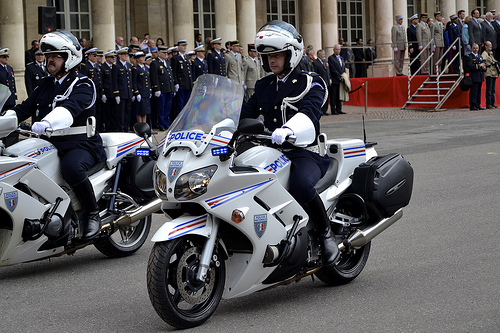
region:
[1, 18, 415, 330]
Pair of policemen on motorcycles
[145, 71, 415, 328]
Red, white, and blue police motorcycle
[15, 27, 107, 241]
Uniformed policeman with moustache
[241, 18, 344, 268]
Motorcycle police officer in formal uniform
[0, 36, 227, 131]
Line of people in blue uniforms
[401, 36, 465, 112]
Set of stairs leading up to platform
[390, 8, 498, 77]
Group of people standing on platform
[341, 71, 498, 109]
Red fabric draping platform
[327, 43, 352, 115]
Standing man in business suit holding beige overcoat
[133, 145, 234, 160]
Blue warning lights on front of motorcycle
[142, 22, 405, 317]
an officer riding the motorcycle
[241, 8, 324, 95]
the helmet is white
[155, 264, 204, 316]
front tire of the motorcycle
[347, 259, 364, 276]
back tire of the motorcycle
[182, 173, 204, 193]
headlights on the car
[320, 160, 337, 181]
the seat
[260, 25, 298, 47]
man is wearing a helmet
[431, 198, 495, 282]
the street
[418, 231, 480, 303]
the street is grey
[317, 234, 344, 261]
the mans foot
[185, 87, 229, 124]
a clear windshield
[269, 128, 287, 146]
man is holding the handle bar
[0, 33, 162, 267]
left police officer on red, white, and blue motorcycle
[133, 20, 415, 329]
right police officer on red, white, and blue motorcycle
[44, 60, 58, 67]
police office on left has moustache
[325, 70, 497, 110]
podium is draped in red cloth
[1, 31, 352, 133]
officers are lined up along the sidewalk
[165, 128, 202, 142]
motorcycle shield is labeled with the word POLICE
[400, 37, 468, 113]
podium has set of portable stairs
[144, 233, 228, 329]
front wheel of motorcycle on right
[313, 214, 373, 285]
rear wheel of motorcycle on right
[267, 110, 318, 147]
police officer on right has white glove and cuff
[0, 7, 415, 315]
two officers riding motorcycles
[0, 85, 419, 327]
two white motorcycles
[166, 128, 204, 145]
blue lettering on white background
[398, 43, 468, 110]
staircase with railing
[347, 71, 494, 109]
red platform in the background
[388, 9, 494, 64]
people standing on red platform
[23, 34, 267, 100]
officers standing at attention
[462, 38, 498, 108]
two men standing in front of platform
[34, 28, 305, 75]
white helmets of the officers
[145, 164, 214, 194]
front lights on motorcycle